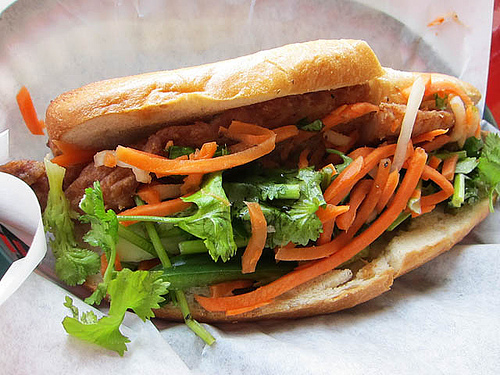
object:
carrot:
[112, 119, 277, 177]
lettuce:
[61, 266, 172, 356]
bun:
[42, 36, 383, 144]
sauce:
[425, 16, 451, 35]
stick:
[137, 220, 218, 350]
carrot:
[323, 157, 366, 239]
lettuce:
[276, 167, 326, 249]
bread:
[105, 188, 492, 322]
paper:
[407, 293, 497, 372]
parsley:
[73, 181, 121, 305]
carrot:
[376, 158, 399, 232]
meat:
[65, 162, 136, 210]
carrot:
[192, 145, 426, 311]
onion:
[387, 70, 434, 172]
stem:
[172, 290, 218, 348]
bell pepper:
[139, 257, 287, 287]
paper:
[227, 335, 389, 373]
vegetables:
[47, 137, 486, 352]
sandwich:
[46, 41, 495, 320]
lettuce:
[121, 174, 236, 262]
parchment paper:
[0, 0, 488, 369]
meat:
[360, 99, 454, 139]